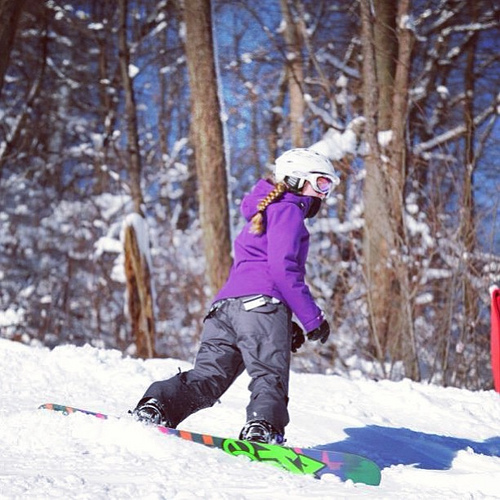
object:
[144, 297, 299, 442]
pants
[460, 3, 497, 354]
tree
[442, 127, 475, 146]
wall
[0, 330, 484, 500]
snow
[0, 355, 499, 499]
ground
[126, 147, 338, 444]
person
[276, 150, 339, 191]
helmet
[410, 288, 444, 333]
light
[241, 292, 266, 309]
card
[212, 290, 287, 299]
waist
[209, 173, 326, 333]
purple sweater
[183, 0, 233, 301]
trunk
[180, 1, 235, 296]
tree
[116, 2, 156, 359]
tree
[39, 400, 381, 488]
snowboard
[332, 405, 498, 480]
shadow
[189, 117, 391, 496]
snowboarder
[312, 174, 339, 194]
goggles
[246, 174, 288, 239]
pony tail